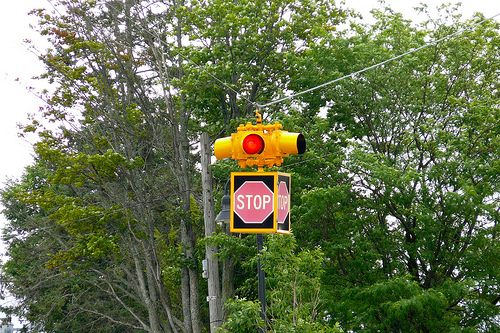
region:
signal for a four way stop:
[197, 90, 333, 253]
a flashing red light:
[184, 109, 321, 164]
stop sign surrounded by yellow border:
[222, 166, 297, 238]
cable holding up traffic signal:
[173, 25, 473, 112]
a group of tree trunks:
[120, 116, 229, 329]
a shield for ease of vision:
[278, 124, 311, 161]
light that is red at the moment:
[225, 114, 272, 171]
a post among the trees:
[247, 241, 274, 328]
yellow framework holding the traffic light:
[196, 114, 311, 173]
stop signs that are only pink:
[227, 173, 295, 239]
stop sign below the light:
[221, 178, 289, 228]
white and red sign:
[237, 183, 273, 217]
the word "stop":
[223, 178, 268, 229]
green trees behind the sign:
[355, 220, 426, 265]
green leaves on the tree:
[366, 278, 428, 319]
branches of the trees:
[99, 225, 176, 323]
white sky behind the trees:
[4, 54, 53, 106]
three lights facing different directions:
[198, 113, 302, 165]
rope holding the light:
[223, 71, 318, 120]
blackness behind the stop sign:
[257, 174, 279, 189]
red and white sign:
[230, 182, 276, 219]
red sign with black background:
[221, 170, 276, 226]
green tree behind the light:
[335, 220, 420, 285]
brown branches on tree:
[91, 195, 201, 285]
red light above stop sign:
[220, 115, 275, 155]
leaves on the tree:
[375, 156, 455, 226]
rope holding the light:
[275, 43, 392, 114]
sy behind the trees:
[323, 11, 386, 41]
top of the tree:
[44, 1, 127, 85]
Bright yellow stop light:
[198, 105, 315, 162]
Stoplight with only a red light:
[191, 105, 328, 170]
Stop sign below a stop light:
[208, 109, 308, 252]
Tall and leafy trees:
[9, 27, 200, 328]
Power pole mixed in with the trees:
[174, 99, 228, 330]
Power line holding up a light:
[73, 0, 498, 165]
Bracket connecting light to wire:
[234, 95, 284, 143]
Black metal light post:
[208, 158, 275, 324]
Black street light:
[210, 173, 243, 233]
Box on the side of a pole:
[191, 247, 219, 289]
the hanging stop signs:
[229, 172, 291, 234]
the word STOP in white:
[237, 192, 268, 210]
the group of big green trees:
[29, 6, 492, 321]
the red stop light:
[243, 134, 262, 154]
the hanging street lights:
[211, 107, 303, 162]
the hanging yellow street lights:
[212, 108, 303, 160]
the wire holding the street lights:
[108, 10, 453, 112]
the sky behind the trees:
[6, 2, 121, 162]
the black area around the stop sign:
[232, 175, 275, 228]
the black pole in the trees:
[253, 235, 272, 330]